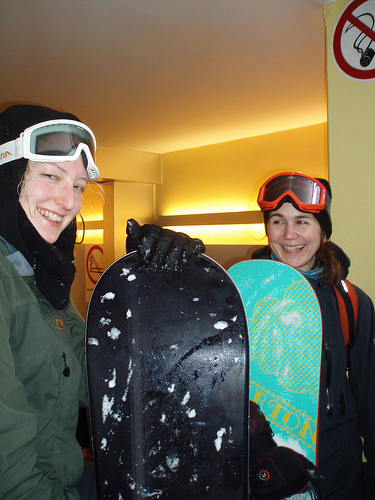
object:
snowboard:
[80, 244, 252, 499]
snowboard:
[225, 254, 322, 499]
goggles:
[255, 171, 331, 217]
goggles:
[0, 116, 101, 179]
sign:
[331, 0, 375, 82]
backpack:
[333, 276, 375, 372]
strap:
[330, 272, 360, 350]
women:
[0, 98, 206, 500]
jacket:
[1, 239, 95, 499]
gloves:
[122, 218, 207, 270]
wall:
[323, 4, 375, 311]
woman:
[249, 170, 375, 499]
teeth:
[52, 213, 57, 221]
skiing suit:
[248, 243, 374, 498]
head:
[258, 173, 333, 269]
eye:
[272, 218, 286, 226]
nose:
[282, 222, 299, 240]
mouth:
[278, 241, 306, 256]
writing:
[250, 379, 316, 453]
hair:
[317, 220, 351, 286]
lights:
[154, 201, 340, 248]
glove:
[250, 414, 315, 499]